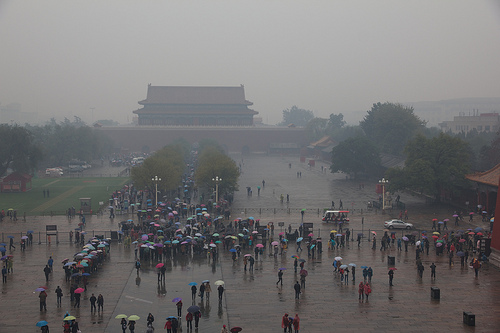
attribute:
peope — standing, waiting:
[2, 157, 498, 333]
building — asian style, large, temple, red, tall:
[136, 84, 259, 125]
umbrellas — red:
[216, 279, 225, 286]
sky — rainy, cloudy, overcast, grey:
[1, 0, 499, 127]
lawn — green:
[3, 173, 129, 217]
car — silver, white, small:
[387, 219, 414, 230]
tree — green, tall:
[332, 138, 384, 179]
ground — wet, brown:
[1, 150, 499, 331]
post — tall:
[378, 178, 390, 211]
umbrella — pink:
[255, 241, 265, 249]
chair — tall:
[322, 210, 352, 226]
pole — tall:
[151, 176, 160, 207]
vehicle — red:
[318, 210, 349, 223]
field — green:
[2, 172, 132, 217]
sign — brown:
[301, 222, 314, 230]